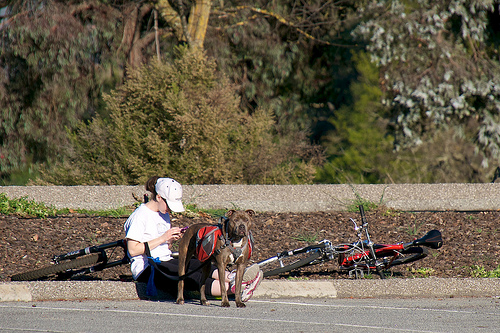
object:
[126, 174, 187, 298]
woman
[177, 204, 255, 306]
brown dog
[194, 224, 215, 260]
backpack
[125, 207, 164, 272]
white shirt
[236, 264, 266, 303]
tennis shoes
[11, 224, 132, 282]
black bike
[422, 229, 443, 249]
black seat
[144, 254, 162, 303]
blue ribbon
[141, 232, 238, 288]
dog leash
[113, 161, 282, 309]
woman and dog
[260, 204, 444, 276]
bike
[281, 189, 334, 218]
ground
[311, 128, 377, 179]
green foliage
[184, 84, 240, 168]
trees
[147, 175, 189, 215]
white hat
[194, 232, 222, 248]
red vest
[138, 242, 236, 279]
black leash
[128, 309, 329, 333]
lot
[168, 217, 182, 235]
phone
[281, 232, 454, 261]
down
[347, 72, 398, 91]
green folliage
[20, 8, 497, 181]
background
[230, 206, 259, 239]
head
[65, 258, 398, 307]
curb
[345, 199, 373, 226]
handle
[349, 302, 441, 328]
concrete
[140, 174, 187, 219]
head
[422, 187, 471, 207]
wall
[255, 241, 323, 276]
black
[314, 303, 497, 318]
white lines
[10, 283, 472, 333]
parking lot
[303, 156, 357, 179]
leafy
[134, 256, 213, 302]
black pants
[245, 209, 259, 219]
brown ears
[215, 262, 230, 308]
brown legs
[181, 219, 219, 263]
red and grey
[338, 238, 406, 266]
red frame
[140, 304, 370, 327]
white stripes